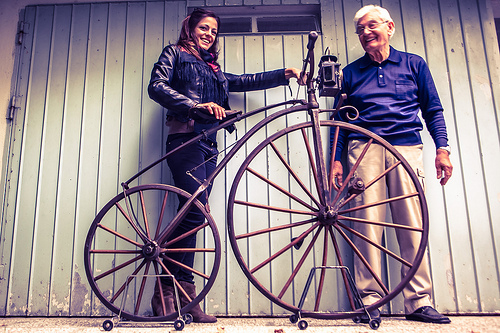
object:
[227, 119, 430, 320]
wheel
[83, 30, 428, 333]
bike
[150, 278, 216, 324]
boots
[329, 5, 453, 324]
man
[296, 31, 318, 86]
handlebars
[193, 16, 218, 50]
face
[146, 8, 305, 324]
woman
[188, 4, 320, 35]
window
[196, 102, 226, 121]
hand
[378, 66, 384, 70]
buttons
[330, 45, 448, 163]
shirt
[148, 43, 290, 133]
leather coat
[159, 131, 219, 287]
tight pants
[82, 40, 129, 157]
door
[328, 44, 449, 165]
blue shirt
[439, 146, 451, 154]
watch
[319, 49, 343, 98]
lantern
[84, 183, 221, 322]
wheel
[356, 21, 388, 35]
glasses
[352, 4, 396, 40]
gray hair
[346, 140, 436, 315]
tan pants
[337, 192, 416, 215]
spokes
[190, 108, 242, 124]
seat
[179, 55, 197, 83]
leather jacket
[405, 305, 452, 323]
loafers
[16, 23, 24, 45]
hinges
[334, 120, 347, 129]
edge